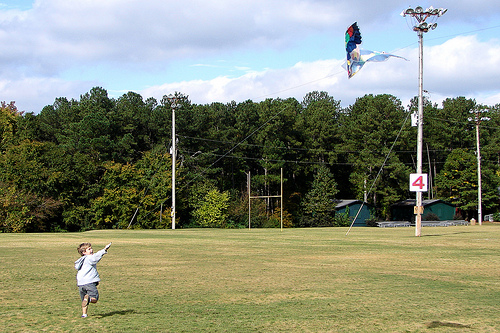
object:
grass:
[0, 224, 500, 333]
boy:
[73, 241, 113, 318]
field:
[0, 223, 500, 333]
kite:
[341, 21, 410, 80]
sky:
[0, 0, 500, 112]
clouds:
[430, 35, 500, 94]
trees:
[250, 140, 290, 220]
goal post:
[248, 167, 283, 231]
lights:
[431, 22, 438, 30]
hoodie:
[74, 249, 109, 286]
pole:
[414, 32, 424, 238]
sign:
[409, 173, 428, 192]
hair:
[77, 242, 91, 256]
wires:
[177, 150, 478, 165]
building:
[335, 199, 371, 227]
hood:
[74, 256, 87, 271]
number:
[412, 176, 425, 189]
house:
[391, 198, 458, 226]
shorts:
[78, 281, 99, 304]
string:
[108, 59, 348, 245]